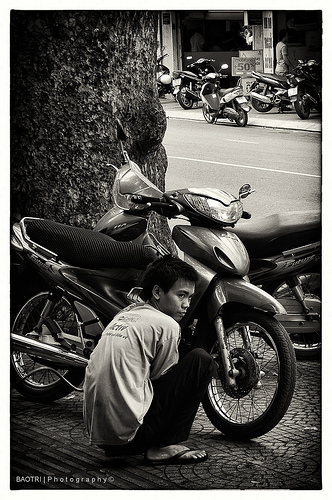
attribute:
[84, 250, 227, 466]
he — worried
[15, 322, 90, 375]
pipe — grey, metal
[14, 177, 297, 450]
motorcycle — modern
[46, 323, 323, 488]
sidewalk — stone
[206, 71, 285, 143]
motorcycles — parked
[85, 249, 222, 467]
man — croutches , young, Asian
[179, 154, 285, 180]
line — white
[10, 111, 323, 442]
motorcycles — parked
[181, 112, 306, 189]
road — black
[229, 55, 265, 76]
sign — grey, black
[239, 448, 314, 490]
bricks — grey